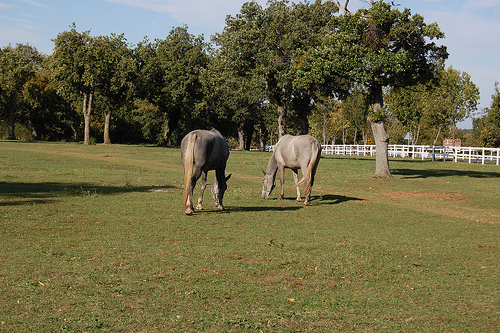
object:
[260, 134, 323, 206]
horse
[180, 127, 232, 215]
horse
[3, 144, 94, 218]
grass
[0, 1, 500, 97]
sky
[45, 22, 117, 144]
tree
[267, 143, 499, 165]
fence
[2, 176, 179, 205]
shadow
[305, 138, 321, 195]
tail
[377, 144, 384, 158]
bark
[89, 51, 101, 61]
leaves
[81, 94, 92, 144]
trunk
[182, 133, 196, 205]
tail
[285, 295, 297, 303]
leaf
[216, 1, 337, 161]
tree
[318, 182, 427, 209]
pathway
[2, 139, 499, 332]
field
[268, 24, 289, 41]
leaves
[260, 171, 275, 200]
head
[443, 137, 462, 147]
building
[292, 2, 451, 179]
tree